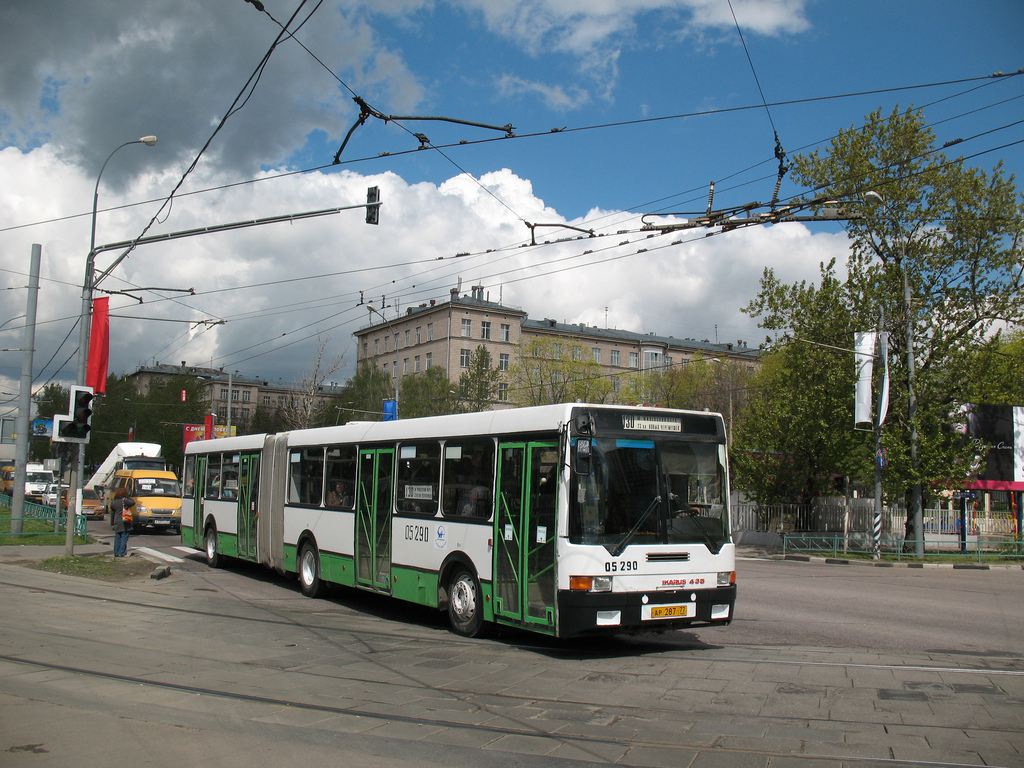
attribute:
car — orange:
[23, 452, 162, 578]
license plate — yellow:
[645, 597, 712, 621]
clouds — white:
[209, 188, 387, 309]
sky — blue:
[6, 1, 1013, 391]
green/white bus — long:
[168, 394, 747, 658]